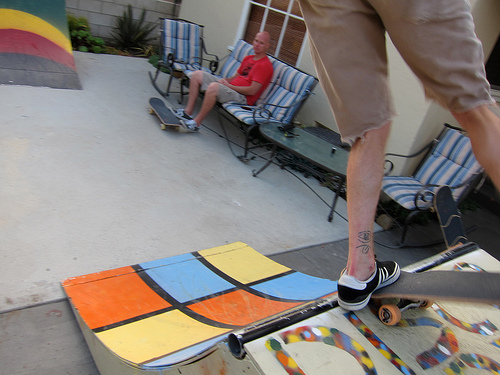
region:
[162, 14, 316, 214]
the guy in red shirt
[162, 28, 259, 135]
the guy in red shirt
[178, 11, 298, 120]
the guy in red shirt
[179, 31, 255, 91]
the guy in red shirt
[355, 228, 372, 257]
TATTOO ON MAN'S LEG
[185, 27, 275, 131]
MAN IN A RED SHIRT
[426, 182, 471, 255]
SKATEBOARD LEANING AGAINST A CHAIR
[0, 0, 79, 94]
SKATEBOARD RAMP IN THE BACKGROUND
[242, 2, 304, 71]
WINDOW WITH 6 PANES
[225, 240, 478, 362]
BLACK SKATE RAMP COPING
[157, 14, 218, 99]
BLUE AND WHITE CHAIR CUSHION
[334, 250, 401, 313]
BLACK AND WHITE SNEAKER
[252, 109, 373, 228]
OUTDOOR PATIO COFFEE TABLE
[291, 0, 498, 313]
SKATEBOARDER ON A RAMP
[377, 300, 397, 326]
An orange skateboard wheel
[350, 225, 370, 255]
A green tattoo on a leg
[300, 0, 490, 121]
The shorts are brown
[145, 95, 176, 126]
A black skateboard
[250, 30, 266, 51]
The man is bald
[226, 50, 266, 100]
The shirt is red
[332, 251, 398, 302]
The shoe is black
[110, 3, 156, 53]
The plant is green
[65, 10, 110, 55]
The plant is green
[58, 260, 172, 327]
The square is orange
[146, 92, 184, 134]
skateboard on concrete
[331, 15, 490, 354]
man on tilted skateboard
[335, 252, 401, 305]
black and white tennis shoe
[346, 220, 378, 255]
tattoo on lower leg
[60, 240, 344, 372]
orange, blue and tellow skateboard ramp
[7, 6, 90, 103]
a rainbow skateboard ramp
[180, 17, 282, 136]
man in red shirt watching skateboarder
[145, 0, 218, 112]
blue and white striped rocking chair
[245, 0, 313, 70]
window on white wall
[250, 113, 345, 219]
outdoor patio coffee table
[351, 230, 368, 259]
part of a tattoo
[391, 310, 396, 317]
wheel of a skate board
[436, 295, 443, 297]
part of a board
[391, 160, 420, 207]
edge of a chair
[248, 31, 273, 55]
face of a man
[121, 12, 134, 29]
part of a plant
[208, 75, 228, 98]
knee of a man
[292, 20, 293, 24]
part of a window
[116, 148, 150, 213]
part of a surface